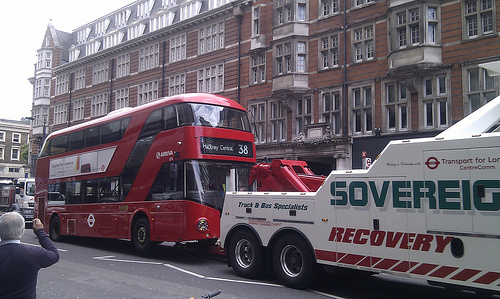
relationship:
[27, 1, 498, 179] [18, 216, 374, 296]
building beside road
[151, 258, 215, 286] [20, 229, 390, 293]
lines are on road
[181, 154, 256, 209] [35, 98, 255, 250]
windshield on bus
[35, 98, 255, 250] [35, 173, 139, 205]
bus has windows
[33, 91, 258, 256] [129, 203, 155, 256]
bus has wheel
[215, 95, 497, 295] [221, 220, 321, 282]
truck has wheels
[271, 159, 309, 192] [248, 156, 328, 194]
mechanism on back of truck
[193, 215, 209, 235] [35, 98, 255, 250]
headlight in front of bus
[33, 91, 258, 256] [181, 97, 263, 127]
bus has window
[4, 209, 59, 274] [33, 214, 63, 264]
man has hand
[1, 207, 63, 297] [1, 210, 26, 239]
man has hair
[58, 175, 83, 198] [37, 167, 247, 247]
side window on level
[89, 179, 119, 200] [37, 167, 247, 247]
side window on level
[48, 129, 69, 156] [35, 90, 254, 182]
window on side of upper level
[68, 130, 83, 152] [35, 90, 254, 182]
window on side of upper level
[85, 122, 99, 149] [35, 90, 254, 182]
window on side of upper level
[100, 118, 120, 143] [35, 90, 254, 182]
window on side of upper level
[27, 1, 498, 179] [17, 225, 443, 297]
building beside street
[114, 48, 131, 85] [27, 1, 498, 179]
window on building